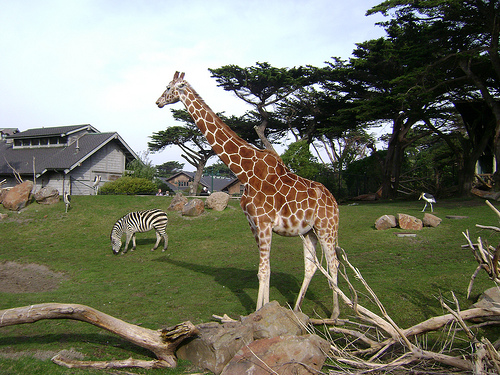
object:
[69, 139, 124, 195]
wall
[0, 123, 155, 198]
building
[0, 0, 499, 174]
sky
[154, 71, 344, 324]
adult giraffe